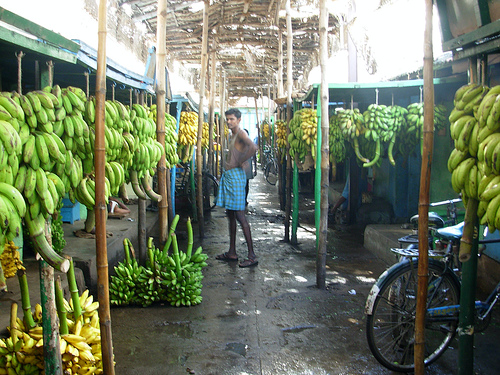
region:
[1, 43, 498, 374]
A large amount of bananas.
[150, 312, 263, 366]
Water on the ground.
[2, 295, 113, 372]
The bananas are yellow.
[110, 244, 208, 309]
The bananas are green.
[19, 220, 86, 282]
The stem is light green.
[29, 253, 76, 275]
Brown on the stem.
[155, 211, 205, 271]
The stems are green.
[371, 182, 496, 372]
There are bikes in the corner.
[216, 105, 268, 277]
A man looking at the camera.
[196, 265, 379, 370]
The ground is brown.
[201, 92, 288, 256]
this is a person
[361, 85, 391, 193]
this is a banana stalk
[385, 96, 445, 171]
this is a banana stalk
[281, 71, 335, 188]
this is a banana stalk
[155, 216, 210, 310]
this is a banana stalk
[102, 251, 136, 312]
this is a banana stalk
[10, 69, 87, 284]
this is a banana stalk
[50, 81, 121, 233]
this is a banana stalk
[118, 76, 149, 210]
this is a banana stalk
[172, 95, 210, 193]
this is a banana stalk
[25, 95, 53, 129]
green banana hanging onto each other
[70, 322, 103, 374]
yellow banana on ground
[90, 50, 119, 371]
tall brown bamboo stick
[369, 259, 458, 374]
back black tire on bike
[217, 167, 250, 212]
checkered blue shorts on man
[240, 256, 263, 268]
left foot on man's leg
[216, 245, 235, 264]
right foot on man's leg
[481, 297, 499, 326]
pedal on the bicycle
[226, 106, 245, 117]
black hair on man's head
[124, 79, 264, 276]
a man in a banana processing facility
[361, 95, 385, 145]
bananas hanging from a hook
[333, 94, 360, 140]
bananas hanging from a hook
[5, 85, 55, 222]
bananas hanging from a hook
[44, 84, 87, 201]
bananas hanging from a hook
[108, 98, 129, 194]
bananas hanging from a hook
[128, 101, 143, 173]
bananas hanging from a hook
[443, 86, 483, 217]
bananas hanging from a hook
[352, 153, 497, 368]
two bicycles under several bunches of bananas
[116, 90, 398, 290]
a man standing between hundreds of bananas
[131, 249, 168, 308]
this is a banana stalk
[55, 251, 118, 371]
this is a banana stalk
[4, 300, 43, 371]
this is a banana stalk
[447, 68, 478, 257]
this is a banana stalk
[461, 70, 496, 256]
this is a banana stalk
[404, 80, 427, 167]
this is a banana stalk